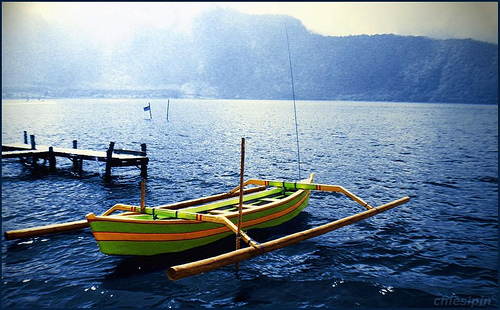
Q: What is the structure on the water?
A: Dock.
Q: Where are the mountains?
A: Across the lake.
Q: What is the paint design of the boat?
A: Striped.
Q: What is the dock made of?
A: Wood.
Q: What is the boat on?
A: Water.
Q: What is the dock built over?
A: Water.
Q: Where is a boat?
A: On the water.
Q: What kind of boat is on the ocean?
A: Green.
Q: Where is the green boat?
A: On sea.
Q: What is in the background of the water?
A: Mountain.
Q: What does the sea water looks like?
A: It's blue.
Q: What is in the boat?
A: Nothing.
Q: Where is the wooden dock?
A: On river.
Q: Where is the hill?
A: Grassy hill in distance.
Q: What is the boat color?
A: Yellow.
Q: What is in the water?
A: Boat.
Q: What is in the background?
A: Mountains.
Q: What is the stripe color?
A: Orange.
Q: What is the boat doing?
A: Anchored.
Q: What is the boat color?
A: Green.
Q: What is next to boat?
A: Deck.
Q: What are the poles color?
A: Yellow.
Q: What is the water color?
A: Blue.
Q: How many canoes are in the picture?
A: One.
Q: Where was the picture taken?
A: By the water.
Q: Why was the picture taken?
A: To capture the canoe.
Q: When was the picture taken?
A: During the day.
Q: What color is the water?
A: Blue.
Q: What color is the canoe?
A: Green and yellow.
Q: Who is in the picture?
A: No one.